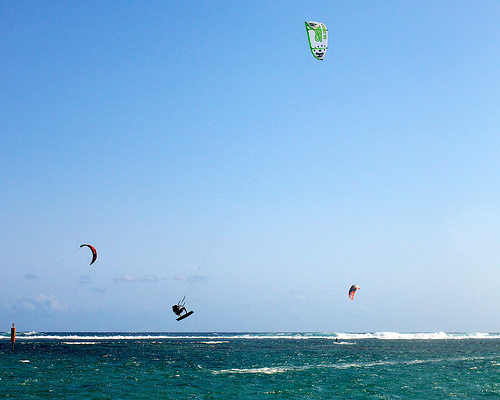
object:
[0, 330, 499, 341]
foam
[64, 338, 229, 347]
wave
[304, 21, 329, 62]
sail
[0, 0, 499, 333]
skies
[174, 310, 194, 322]
board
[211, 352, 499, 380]
foam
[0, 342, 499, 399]
foreground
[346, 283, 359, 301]
kite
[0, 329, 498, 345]
white waves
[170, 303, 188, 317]
skier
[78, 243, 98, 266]
parasail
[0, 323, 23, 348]
floater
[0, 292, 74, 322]
clouds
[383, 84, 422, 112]
ground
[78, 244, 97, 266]
kite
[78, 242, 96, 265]
sail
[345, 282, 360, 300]
sail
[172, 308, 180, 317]
vest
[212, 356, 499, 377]
white surf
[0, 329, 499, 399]
ocean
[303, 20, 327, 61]
kite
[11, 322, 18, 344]
pole